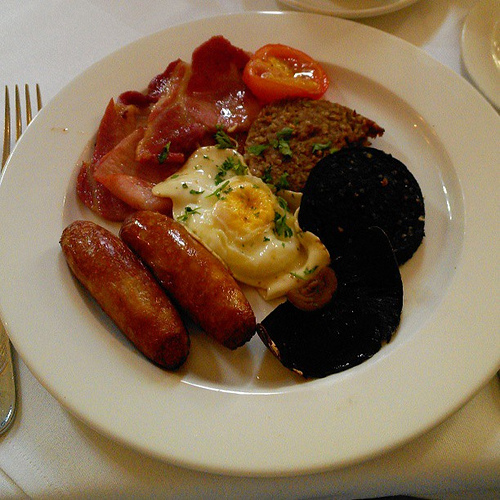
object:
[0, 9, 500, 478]
plate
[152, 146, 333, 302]
egg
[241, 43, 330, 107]
tomato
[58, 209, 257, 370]
sausages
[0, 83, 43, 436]
fork